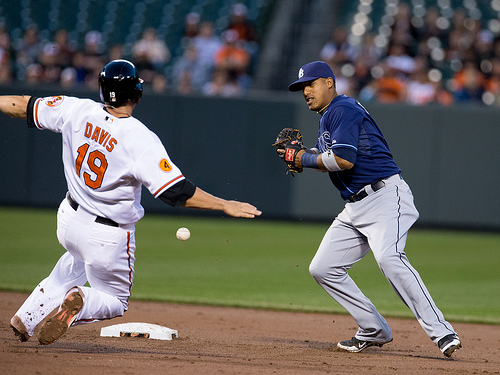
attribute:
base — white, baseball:
[104, 318, 189, 344]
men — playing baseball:
[38, 58, 454, 345]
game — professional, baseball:
[8, 4, 500, 356]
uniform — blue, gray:
[315, 114, 419, 369]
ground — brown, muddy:
[2, 211, 495, 375]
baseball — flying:
[177, 228, 196, 245]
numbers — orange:
[80, 149, 103, 181]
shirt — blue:
[305, 107, 397, 192]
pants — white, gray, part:
[322, 186, 443, 336]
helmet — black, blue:
[96, 64, 132, 89]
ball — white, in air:
[168, 229, 194, 244]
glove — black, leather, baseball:
[276, 120, 303, 164]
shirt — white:
[36, 105, 155, 225]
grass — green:
[3, 209, 466, 310]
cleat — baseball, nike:
[336, 328, 378, 357]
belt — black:
[336, 171, 411, 206]